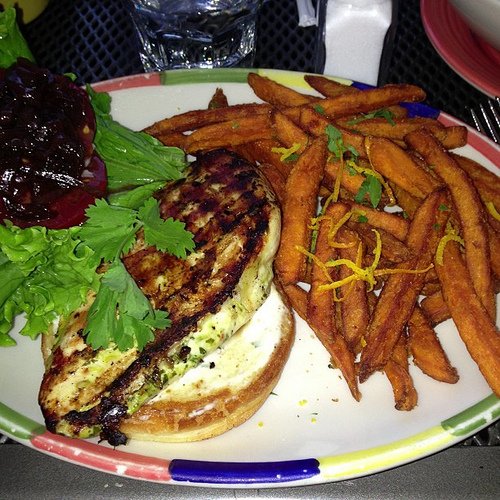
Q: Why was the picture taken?
A: To show the food.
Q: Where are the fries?
A: On the right.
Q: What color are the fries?
A: Brown.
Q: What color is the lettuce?
A: Green.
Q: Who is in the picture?
A: No one.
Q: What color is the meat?
A: Yellow and brown.